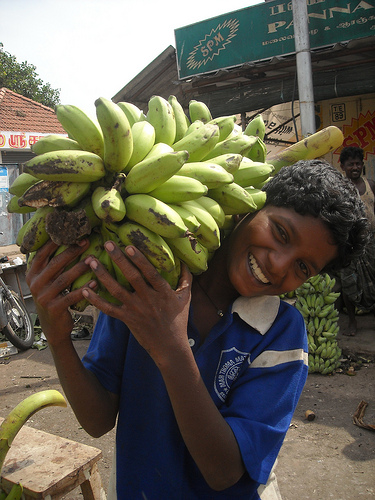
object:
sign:
[173, 3, 371, 81]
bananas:
[322, 332, 335, 338]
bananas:
[25, 150, 106, 181]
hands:
[81, 239, 195, 348]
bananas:
[211, 183, 257, 216]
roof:
[0, 83, 70, 134]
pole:
[287, 0, 316, 138]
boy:
[27, 161, 371, 500]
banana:
[203, 134, 259, 161]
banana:
[123, 150, 189, 195]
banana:
[125, 194, 195, 238]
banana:
[117, 224, 175, 272]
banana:
[92, 184, 126, 222]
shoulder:
[107, 263, 206, 346]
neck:
[196, 254, 237, 314]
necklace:
[202, 279, 225, 318]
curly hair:
[257, 160, 374, 270]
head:
[225, 160, 366, 298]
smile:
[248, 248, 275, 287]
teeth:
[249, 256, 268, 284]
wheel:
[1, 291, 34, 348]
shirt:
[82, 294, 308, 497]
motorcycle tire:
[0, 268, 33, 354]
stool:
[1, 414, 105, 500]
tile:
[6, 93, 17, 106]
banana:
[94, 97, 134, 172]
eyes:
[270, 219, 288, 242]